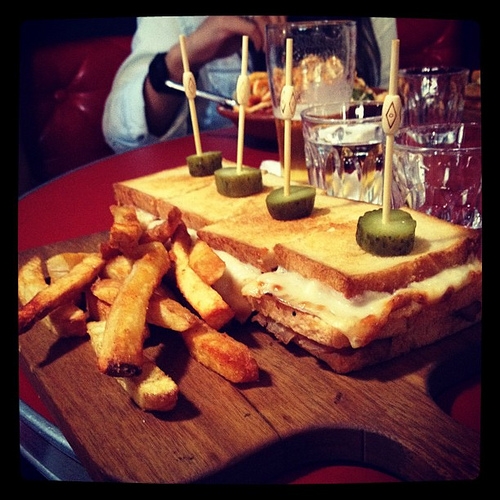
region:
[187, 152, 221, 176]
the pickle on the sandwich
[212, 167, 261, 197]
the pickle on the sandwich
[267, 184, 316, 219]
the pickle on the sandwich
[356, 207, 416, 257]
the pickle on the sandwich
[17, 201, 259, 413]
the pile of fries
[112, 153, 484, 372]
the sandwiches on the wooden board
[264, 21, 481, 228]
the glass cups on the table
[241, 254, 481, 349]
the melted cheese in the sandwich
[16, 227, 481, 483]
the wooden board on the table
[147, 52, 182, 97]
the black item on the person's wrist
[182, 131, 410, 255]
pickles on th bread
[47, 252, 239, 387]
fries on the board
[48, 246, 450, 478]
the cutting board on the table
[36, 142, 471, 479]
the round red table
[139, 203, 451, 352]
melted cheese on the sandwich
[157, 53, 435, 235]
the skicks in the pickles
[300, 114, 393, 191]
the glass with water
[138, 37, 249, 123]
the ladys bare arm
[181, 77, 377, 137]
the ladys bowl of food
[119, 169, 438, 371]
the sandwiches on the board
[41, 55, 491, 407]
a sandwich on a wood plate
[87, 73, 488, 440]
a sandwich cut into fours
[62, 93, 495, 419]
a sandwich on toasted bread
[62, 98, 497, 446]
a sandwich with cheese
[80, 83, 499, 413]
a sandwich with melted cheese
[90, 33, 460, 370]
a sandwich with toothpicks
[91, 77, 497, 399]
a sandwich with four toothpicks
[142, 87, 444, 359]
a sandwich with sliced pickles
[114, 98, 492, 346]
a sandwich with four pickles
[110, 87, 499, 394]
a sandwich with four sliced pickles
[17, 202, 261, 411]
Pile of french fries lying on a wood board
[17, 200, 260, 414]
French fries on a table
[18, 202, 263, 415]
Fries laying on a serving tray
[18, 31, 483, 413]
French fries and a sandwich on a serving platter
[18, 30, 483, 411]
A sandwich and fries on a table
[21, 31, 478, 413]
French fries and a sandwich on a wood board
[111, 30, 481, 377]
Sandwich sitting a wood platter on a table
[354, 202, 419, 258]
Pickle skewered on a sandwich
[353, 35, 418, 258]
Pickle held down with a skewer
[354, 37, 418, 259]
Wood skewer securing pickle to a sandwich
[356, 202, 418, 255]
the pickle is green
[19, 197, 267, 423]
the fries are on a cutting board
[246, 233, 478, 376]
the sandwich is on the cutting board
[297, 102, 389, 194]
the glass is full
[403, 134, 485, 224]
the glass is empty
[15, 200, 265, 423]
the fries are brown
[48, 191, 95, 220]
the table is red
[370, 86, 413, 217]
the toothpick is through the pickle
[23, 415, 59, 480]
the edge of the table is silver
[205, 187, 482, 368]
the cheese on the sandwich is melted